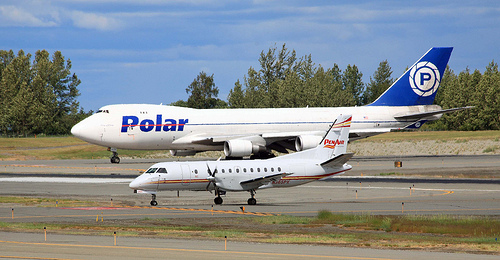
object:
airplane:
[69, 45, 479, 165]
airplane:
[126, 112, 356, 207]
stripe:
[144, 175, 322, 184]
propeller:
[212, 165, 218, 177]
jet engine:
[224, 139, 266, 158]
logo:
[120, 113, 190, 133]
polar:
[120, 112, 189, 132]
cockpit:
[144, 161, 183, 178]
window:
[146, 167, 158, 174]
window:
[157, 168, 168, 173]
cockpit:
[95, 104, 124, 118]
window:
[106, 110, 109, 113]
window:
[96, 110, 103, 113]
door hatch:
[180, 162, 192, 186]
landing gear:
[109, 148, 122, 164]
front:
[69, 102, 187, 149]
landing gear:
[149, 190, 158, 206]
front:
[128, 160, 193, 207]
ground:
[1, 143, 500, 258]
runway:
[1, 153, 499, 176]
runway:
[0, 176, 499, 221]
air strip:
[1, 231, 498, 260]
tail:
[361, 46, 455, 106]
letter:
[420, 72, 432, 85]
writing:
[324, 138, 345, 145]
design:
[407, 61, 439, 97]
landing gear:
[213, 187, 224, 204]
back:
[161, 113, 350, 166]